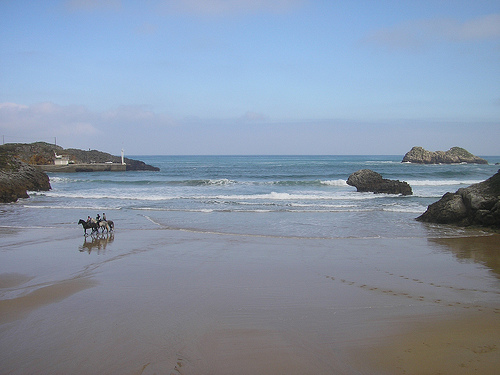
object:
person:
[102, 213, 107, 222]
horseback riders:
[86, 215, 91, 227]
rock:
[347, 169, 414, 195]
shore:
[1, 205, 498, 375]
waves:
[71, 176, 324, 190]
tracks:
[340, 277, 347, 283]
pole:
[121, 149, 124, 165]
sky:
[0, 0, 499, 155]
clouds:
[372, 10, 500, 44]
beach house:
[53, 153, 71, 167]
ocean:
[23, 154, 482, 212]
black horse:
[78, 219, 100, 236]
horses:
[91, 217, 110, 234]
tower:
[54, 137, 57, 146]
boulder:
[345, 168, 413, 196]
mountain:
[0, 141, 160, 172]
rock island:
[401, 146, 489, 165]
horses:
[100, 220, 115, 233]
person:
[96, 214, 101, 228]